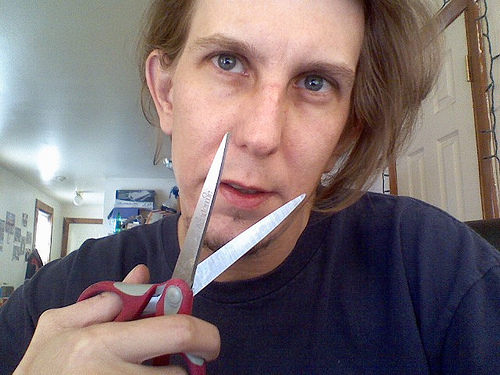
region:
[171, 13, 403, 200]
the head of a man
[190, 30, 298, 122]
the eyes of a man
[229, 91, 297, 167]
the nose of a man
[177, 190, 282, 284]
the chin of a man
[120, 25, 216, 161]
the ear of a man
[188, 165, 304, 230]
the lips of a man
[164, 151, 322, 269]
the teeth of a man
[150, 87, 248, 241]
the cheek of a man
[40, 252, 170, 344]
the thumb of a man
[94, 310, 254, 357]
the finger of a man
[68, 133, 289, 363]
A pair of scissors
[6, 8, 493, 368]
A person holding scissors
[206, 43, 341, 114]
A blue set of eyes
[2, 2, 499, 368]
A man holding scissors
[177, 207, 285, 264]
A bear on a persons chin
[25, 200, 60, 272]
A window with light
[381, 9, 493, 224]
A white door with brown trim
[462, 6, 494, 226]
Brown trim on a doorway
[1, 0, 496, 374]
Person wearing blue shirt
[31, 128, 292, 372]
Hand holding scissors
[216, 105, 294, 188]
the nose of a woman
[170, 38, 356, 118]
the eyes of a woman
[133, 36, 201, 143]
the ears of a woman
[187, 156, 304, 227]
the lips of a woman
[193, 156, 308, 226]
the teeth of a woman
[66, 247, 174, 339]
the thumb of a woman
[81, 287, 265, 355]
the finger of a woman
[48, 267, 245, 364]
the hand of a woman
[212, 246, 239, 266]
the scissors are silver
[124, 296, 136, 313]
the handle is maroon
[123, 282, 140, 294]
the handle is gray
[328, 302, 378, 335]
the shirt is blue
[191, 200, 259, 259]
the scissors are open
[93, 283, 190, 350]
he is holding the scissors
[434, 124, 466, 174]
the door is white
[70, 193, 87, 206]
the light is off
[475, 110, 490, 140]
the frame is brown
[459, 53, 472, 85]
the hinge is gold